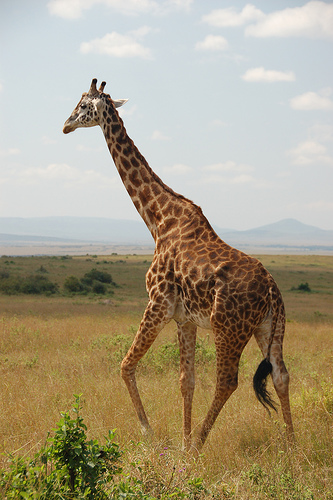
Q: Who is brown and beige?
A: Giraffe.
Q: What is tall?
A: A giraffe.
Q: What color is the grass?
A: Green.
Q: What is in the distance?
A: Mountains.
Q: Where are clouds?
A: In the sky.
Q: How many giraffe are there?
A: One.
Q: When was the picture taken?
A: Daytime.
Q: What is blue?
A: Sky.